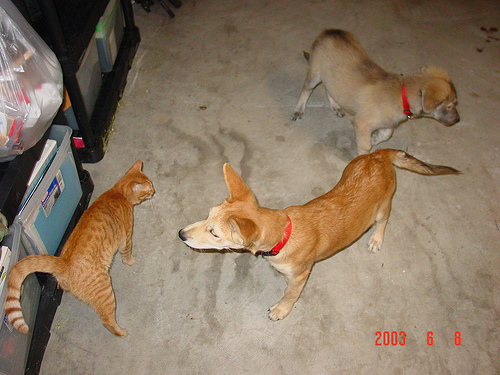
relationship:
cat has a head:
[4, 161, 156, 338] [119, 162, 156, 204]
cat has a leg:
[4, 161, 156, 338] [88, 269, 127, 337]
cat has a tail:
[4, 161, 156, 338] [2, 255, 57, 334]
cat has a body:
[4, 161, 156, 338] [63, 194, 134, 289]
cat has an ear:
[4, 161, 156, 338] [131, 160, 143, 171]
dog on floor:
[179, 146, 463, 322] [39, 2, 499, 373]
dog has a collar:
[179, 146, 463, 322] [398, 74, 413, 116]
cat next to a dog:
[4, 161, 156, 338] [179, 146, 463, 322]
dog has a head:
[179, 146, 463, 322] [178, 196, 259, 255]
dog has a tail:
[179, 146, 463, 322] [380, 146, 461, 176]